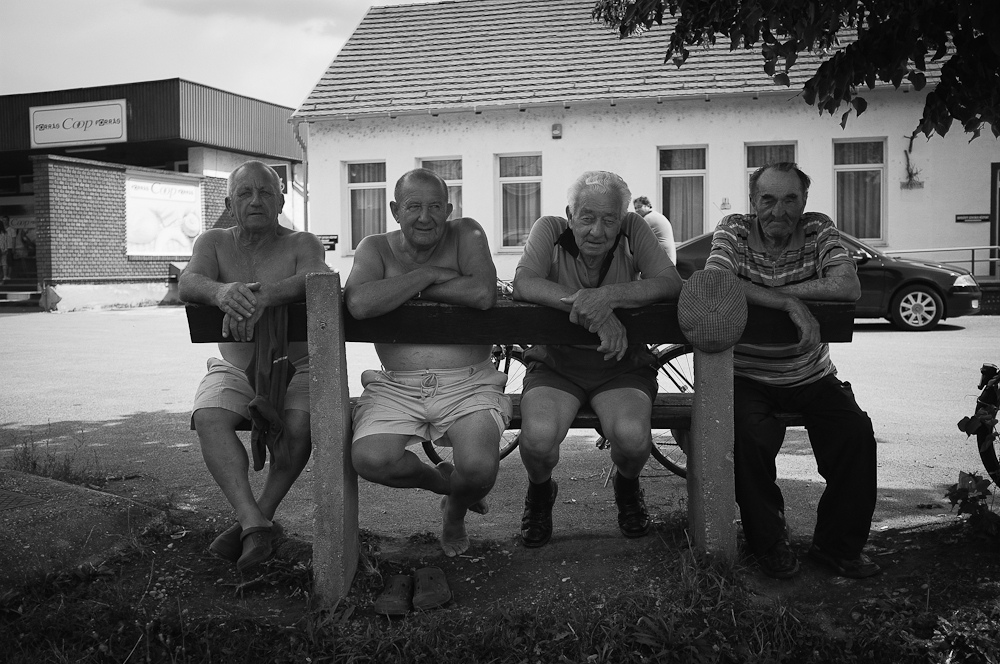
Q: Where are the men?
A: On a bench in front of a store.